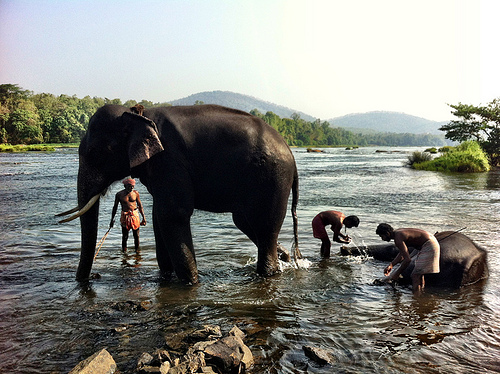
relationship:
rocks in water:
[75, 323, 257, 372] [0, 142, 498, 370]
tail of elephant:
[289, 162, 301, 251] [53, 103, 302, 284]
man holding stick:
[109, 178, 147, 253] [90, 221, 115, 275]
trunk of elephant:
[74, 164, 99, 281] [53, 103, 302, 284]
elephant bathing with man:
[53, 103, 302, 284] [109, 178, 147, 253]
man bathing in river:
[109, 178, 147, 253] [1, 146, 499, 371]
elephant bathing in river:
[53, 103, 302, 284] [1, 146, 499, 371]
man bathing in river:
[311, 210, 360, 258] [1, 146, 499, 371]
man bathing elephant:
[308, 205, 361, 264] [338, 223, 489, 298]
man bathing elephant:
[375, 220, 440, 296] [338, 223, 489, 298]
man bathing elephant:
[106, 170, 146, 258] [50, 98, 304, 285]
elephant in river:
[50, 98, 304, 285] [1, 146, 499, 371]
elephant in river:
[338, 223, 489, 298] [1, 146, 499, 371]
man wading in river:
[109, 178, 147, 253] [1, 146, 499, 371]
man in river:
[375, 222, 440, 295] [1, 146, 499, 371]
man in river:
[311, 210, 360, 258] [1, 146, 499, 371]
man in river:
[106, 170, 146, 258] [1, 146, 499, 371]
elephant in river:
[338, 230, 489, 288] [1, 146, 499, 371]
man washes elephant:
[311, 210, 360, 258] [53, 103, 302, 284]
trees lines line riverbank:
[0, 84, 455, 149] [1, 145, 78, 150]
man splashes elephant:
[311, 210, 360, 258] [53, 103, 302, 284]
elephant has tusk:
[50, 98, 304, 285] [58, 193, 99, 224]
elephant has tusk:
[50, 98, 304, 285] [54, 205, 79, 223]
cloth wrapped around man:
[413, 240, 444, 272] [376, 227, 437, 286]